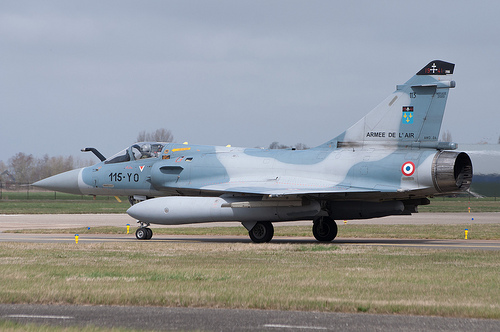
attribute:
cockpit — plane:
[104, 141, 160, 166]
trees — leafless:
[0, 120, 498, 200]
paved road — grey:
[0, 300, 500, 330]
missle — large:
[49, 111, 452, 282]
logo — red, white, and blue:
[400, 160, 415, 180]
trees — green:
[0, 152, 99, 189]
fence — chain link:
[1, 181, 44, 195]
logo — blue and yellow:
[402, 105, 415, 122]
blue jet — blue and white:
[24, 53, 486, 273]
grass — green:
[1, 244, 498, 314]